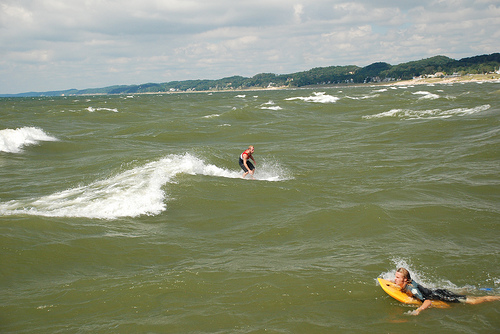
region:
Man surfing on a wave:
[219, 140, 288, 185]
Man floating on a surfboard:
[372, 257, 492, 324]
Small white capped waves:
[65, 146, 210, 234]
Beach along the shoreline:
[381, 65, 483, 92]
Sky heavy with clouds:
[5, 9, 462, 89]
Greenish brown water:
[115, 214, 332, 314]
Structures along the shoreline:
[290, 74, 426, 86]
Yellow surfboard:
[367, 277, 457, 320]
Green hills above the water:
[216, 45, 457, 81]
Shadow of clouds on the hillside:
[295, 57, 442, 90]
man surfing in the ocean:
[225, 137, 267, 185]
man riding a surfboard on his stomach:
[368, 251, 498, 324]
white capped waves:
[15, 155, 177, 222]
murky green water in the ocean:
[85, 240, 325, 313]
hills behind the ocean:
[12, 57, 470, 100]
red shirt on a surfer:
[234, 144, 257, 170]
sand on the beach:
[412, 72, 498, 87]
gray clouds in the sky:
[17, 12, 258, 62]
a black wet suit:
[401, 275, 475, 302]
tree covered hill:
[310, 63, 359, 81]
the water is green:
[16, 87, 491, 332]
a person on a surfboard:
[365, 262, 496, 327]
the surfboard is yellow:
[369, 263, 443, 316]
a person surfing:
[211, 113, 279, 197]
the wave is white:
[31, 128, 278, 263]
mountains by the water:
[25, 41, 498, 92]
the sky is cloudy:
[0, 0, 498, 93]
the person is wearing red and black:
[229, 124, 273, 192]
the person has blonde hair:
[368, 255, 496, 320]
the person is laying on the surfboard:
[349, 243, 499, 318]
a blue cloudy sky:
[0, 2, 497, 90]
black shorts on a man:
[237, 156, 252, 167]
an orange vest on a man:
[236, 145, 253, 155]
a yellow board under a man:
[375, 270, 456, 310]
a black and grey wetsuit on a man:
[400, 276, 465, 306]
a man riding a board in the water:
[371, 263, 497, 318]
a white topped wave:
[18, 147, 197, 225]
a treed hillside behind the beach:
[415, 48, 495, 74]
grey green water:
[3, 83, 495, 332]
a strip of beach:
[394, 75, 497, 85]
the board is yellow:
[371, 272, 393, 304]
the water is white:
[97, 161, 145, 211]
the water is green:
[137, 230, 273, 280]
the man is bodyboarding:
[367, 253, 495, 318]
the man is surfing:
[237, 141, 260, 181]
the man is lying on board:
[376, 250, 491, 322]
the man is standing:
[236, 140, 262, 187]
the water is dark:
[117, 255, 248, 298]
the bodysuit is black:
[413, 272, 465, 308]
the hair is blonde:
[395, 265, 411, 275]